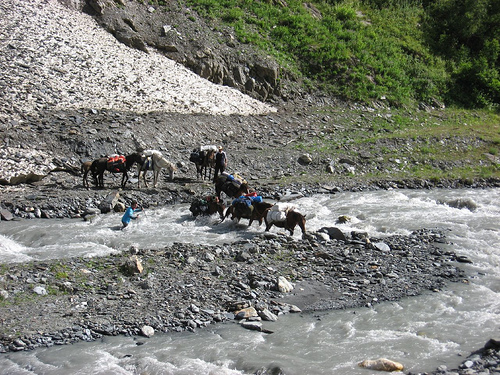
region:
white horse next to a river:
[145, 139, 179, 180]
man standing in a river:
[115, 193, 146, 242]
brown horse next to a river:
[85, 141, 147, 191]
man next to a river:
[214, 143, 231, 180]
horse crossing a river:
[261, 192, 306, 234]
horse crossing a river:
[185, 182, 217, 229]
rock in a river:
[356, 350, 399, 374]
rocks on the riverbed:
[228, 290, 308, 333]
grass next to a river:
[392, 132, 494, 185]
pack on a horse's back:
[265, 198, 295, 224]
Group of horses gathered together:
[99, 128, 342, 264]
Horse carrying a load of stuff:
[265, 200, 310, 235]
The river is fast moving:
[329, 289, 469, 362]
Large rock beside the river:
[219, 266, 306, 347]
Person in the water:
[102, 197, 152, 239]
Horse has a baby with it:
[83, 149, 143, 191]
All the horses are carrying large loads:
[59, 125, 316, 249]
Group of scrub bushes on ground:
[281, 12, 498, 119]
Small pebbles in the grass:
[262, 82, 387, 166]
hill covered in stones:
[3, 14, 161, 111]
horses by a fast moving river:
[74, 138, 314, 241]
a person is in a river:
[114, 195, 151, 232]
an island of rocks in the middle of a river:
[2, 225, 475, 373]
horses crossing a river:
[188, 191, 311, 241]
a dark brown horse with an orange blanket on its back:
[89, 150, 144, 188]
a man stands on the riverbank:
[209, 144, 233, 186]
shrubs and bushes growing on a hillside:
[192, 0, 454, 112]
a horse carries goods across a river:
[260, 198, 309, 241]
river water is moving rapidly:
[0, 186, 498, 373]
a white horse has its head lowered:
[132, 147, 177, 192]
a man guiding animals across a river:
[106, 195, 143, 230]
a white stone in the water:
[357, 353, 401, 373]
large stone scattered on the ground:
[334, 246, 392, 291]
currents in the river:
[369, 312, 429, 344]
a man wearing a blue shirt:
[116, 198, 148, 231]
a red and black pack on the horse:
[105, 148, 127, 170]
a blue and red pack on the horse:
[239, 190, 260, 205]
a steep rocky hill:
[39, 17, 262, 114]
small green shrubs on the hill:
[311, 19, 404, 92]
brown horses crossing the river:
[199, 145, 317, 255]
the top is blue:
[113, 209, 143, 230]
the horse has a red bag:
[85, 153, 140, 188]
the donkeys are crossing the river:
[217, 169, 314, 236]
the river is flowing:
[378, 170, 485, 372]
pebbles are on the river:
[230, 234, 390, 296]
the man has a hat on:
[213, 141, 232, 179]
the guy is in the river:
[114, 188, 157, 237]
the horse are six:
[58, 132, 328, 257]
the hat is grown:
[211, 139, 238, 174]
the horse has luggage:
[224, 189, 276, 248]